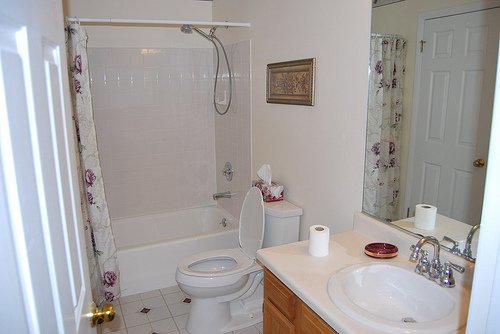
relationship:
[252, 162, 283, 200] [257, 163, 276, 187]
box of paper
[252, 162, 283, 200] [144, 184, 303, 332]
box on commode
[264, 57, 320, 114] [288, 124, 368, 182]
decor hanging on wall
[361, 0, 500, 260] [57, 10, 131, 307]
reflection of shower curtain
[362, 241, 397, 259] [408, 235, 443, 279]
soap dish beside faucet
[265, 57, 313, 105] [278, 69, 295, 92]
framed picture of flower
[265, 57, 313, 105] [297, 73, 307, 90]
framed picture of flower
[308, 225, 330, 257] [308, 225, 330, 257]
paper of paper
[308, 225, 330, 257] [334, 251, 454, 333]
paper sitting by sink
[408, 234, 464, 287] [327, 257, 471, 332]
faucet on sink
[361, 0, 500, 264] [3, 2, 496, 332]
mirror reflecting room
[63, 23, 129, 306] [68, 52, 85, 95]
curtain with purple roses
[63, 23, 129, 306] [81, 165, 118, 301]
curtain with purple roses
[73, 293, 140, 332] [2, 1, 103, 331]
handle on door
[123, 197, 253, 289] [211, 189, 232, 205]
bathtub with faucet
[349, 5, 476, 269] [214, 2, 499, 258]
mirror on wall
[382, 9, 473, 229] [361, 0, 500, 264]
reflection in mirror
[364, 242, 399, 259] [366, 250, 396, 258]
soap dish with stripe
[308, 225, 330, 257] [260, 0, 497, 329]
paper on vanity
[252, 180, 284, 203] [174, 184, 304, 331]
box on back of toilet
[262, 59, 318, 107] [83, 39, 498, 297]
picture above toilet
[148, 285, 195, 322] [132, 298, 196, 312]
floor with diamonds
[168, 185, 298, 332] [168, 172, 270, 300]
toilet has seat up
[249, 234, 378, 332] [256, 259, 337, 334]
vanity has cabinet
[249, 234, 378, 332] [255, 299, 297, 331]
vanity has cabinet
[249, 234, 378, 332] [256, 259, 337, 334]
vanity with cabinet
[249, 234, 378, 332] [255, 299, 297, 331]
vanity with cabinet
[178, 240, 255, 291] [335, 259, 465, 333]
sits on side of sink